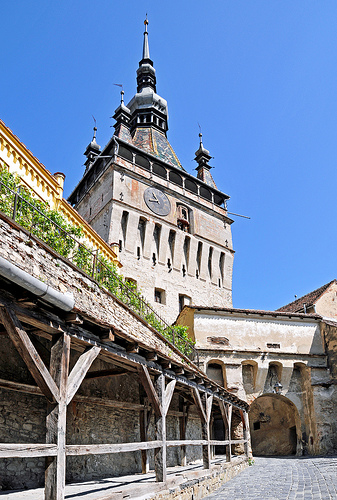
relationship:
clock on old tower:
[141, 181, 177, 220] [63, 2, 242, 316]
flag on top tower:
[136, 8, 155, 23] [63, 2, 242, 316]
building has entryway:
[1, 5, 336, 480] [239, 384, 312, 464]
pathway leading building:
[238, 448, 336, 499] [1, 5, 336, 480]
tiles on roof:
[1, 172, 201, 361] [3, 187, 256, 407]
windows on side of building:
[130, 271, 188, 315] [1, 5, 336, 480]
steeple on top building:
[97, 10, 202, 173] [1, 5, 336, 480]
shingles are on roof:
[0, 223, 123, 297] [3, 187, 256, 407]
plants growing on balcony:
[2, 176, 118, 267] [5, 167, 136, 298]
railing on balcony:
[9, 187, 162, 312] [5, 167, 136, 298]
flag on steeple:
[136, 8, 155, 23] [97, 10, 202, 173]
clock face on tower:
[141, 181, 177, 220] [97, 10, 202, 173]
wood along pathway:
[2, 316, 261, 481] [238, 448, 336, 499]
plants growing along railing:
[0, 162, 83, 274] [9, 187, 162, 312]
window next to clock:
[170, 198, 202, 237] [141, 181, 177, 220]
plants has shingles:
[0, 162, 83, 274] [0, 223, 123, 297]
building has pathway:
[1, 5, 336, 480] [238, 448, 336, 499]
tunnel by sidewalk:
[239, 384, 312, 464] [238, 448, 336, 499]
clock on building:
[141, 181, 177, 220] [1, 5, 336, 480]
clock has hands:
[141, 181, 177, 220] [145, 189, 166, 208]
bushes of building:
[2, 176, 118, 267] [2, 140, 231, 484]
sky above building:
[231, 5, 336, 268] [1, 5, 336, 480]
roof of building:
[3, 187, 256, 407] [2, 140, 231, 484]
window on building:
[170, 198, 202, 237] [1, 5, 336, 480]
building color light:
[1, 5, 336, 480] [85, 165, 252, 297]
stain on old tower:
[127, 172, 144, 201] [63, 9, 235, 324]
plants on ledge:
[2, 176, 118, 267] [23, 158, 122, 254]